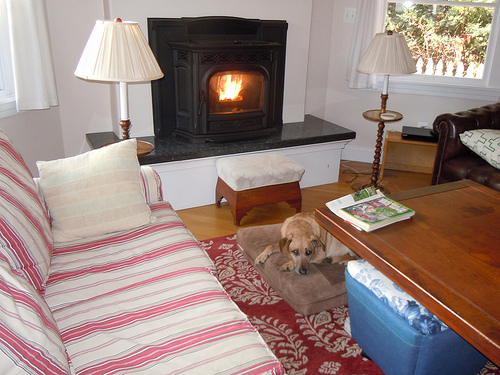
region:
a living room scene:
[19, 32, 437, 354]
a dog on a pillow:
[253, 210, 375, 286]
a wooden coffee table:
[329, 179, 494, 359]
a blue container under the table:
[330, 258, 455, 371]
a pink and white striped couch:
[4, 150, 221, 367]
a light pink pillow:
[34, 134, 150, 234]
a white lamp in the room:
[73, 6, 172, 132]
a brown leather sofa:
[429, 97, 499, 174]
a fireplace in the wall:
[157, 13, 310, 142]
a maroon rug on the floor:
[217, 242, 363, 364]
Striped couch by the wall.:
[0, 129, 293, 373]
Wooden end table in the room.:
[313, 174, 498, 370]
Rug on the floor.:
[195, 225, 385, 374]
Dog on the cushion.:
[251, 213, 362, 273]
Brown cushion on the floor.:
[231, 213, 353, 313]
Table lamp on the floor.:
[353, 28, 415, 202]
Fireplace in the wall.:
[149, 14, 291, 145]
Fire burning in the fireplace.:
[205, 66, 262, 114]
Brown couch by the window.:
[426, 90, 498, 196]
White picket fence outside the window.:
[408, 52, 489, 80]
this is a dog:
[275, 200, 322, 267]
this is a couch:
[23, 237, 197, 344]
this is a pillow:
[65, 158, 137, 225]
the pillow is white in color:
[78, 175, 135, 222]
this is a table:
[413, 205, 496, 297]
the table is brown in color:
[431, 208, 487, 280]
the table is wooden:
[405, 220, 483, 292]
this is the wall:
[293, 6, 337, 90]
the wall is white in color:
[71, 90, 102, 125]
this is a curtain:
[8, 13, 54, 92]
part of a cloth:
[202, 313, 217, 329]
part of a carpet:
[265, 298, 285, 340]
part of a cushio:
[301, 268, 318, 289]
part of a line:
[94, 173, 164, 231]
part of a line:
[430, 275, 442, 294]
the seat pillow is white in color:
[60, 166, 139, 226]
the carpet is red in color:
[269, 303, 349, 373]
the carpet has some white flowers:
[289, 315, 345, 373]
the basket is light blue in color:
[350, 283, 409, 362]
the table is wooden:
[442, 223, 497, 300]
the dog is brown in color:
[276, 207, 333, 290]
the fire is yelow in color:
[210, 76, 270, 122]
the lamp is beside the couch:
[96, 19, 159, 88]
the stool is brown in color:
[218, 177, 307, 209]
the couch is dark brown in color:
[429, 121, 467, 183]